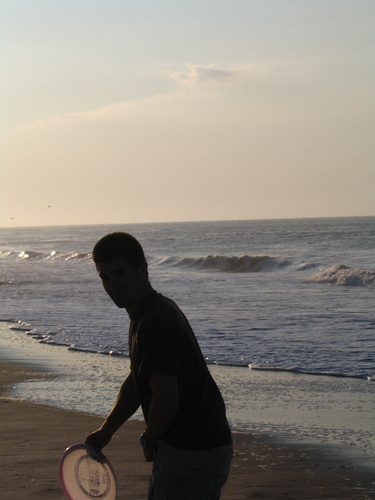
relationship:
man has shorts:
[70, 228, 239, 500] [144, 440, 233, 497]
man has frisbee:
[70, 228, 239, 500] [51, 442, 117, 500]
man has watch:
[70, 228, 239, 500] [137, 425, 156, 450]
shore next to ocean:
[5, 312, 374, 494] [1, 211, 374, 375]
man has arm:
[70, 228, 239, 500] [131, 328, 181, 462]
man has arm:
[70, 228, 239, 500] [80, 365, 138, 467]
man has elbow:
[70, 228, 239, 500] [148, 392, 180, 413]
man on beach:
[70, 228, 239, 500] [3, 232, 368, 488]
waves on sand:
[8, 242, 364, 380] [5, 312, 374, 494]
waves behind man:
[8, 242, 364, 380] [70, 228, 239, 500]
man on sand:
[70, 228, 239, 500] [7, 329, 372, 494]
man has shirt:
[70, 228, 239, 500] [116, 296, 232, 444]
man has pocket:
[70, 228, 239, 500] [166, 453, 222, 482]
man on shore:
[70, 228, 239, 500] [5, 312, 374, 494]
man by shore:
[70, 228, 239, 500] [5, 312, 374, 494]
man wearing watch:
[70, 228, 239, 500] [137, 425, 156, 450]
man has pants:
[70, 228, 239, 500] [144, 440, 233, 497]